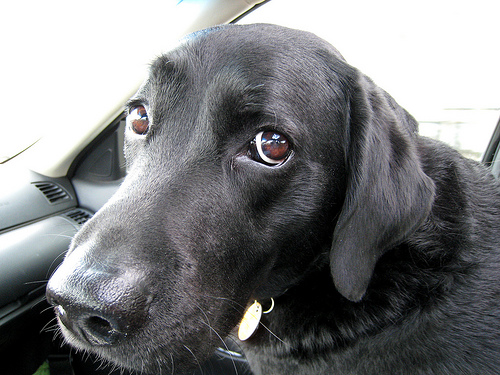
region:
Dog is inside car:
[7, 13, 487, 369]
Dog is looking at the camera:
[1, 19, 497, 372]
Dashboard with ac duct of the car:
[0, 161, 102, 296]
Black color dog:
[26, 50, 481, 367]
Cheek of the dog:
[189, 198, 243, 273]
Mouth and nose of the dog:
[41, 265, 197, 365]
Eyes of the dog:
[133, 96, 295, 176]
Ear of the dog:
[323, 79, 443, 332]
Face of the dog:
[28, 32, 406, 352]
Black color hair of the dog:
[446, 150, 490, 331]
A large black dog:
[45, 23, 495, 373]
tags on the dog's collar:
[235, 295, 270, 335]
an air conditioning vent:
[65, 205, 90, 220]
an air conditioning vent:
[31, 180, 67, 202]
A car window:
[236, 0, 496, 161]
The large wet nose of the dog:
[45, 260, 140, 345]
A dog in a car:
[42, 23, 496, 373]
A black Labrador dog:
[42, 20, 498, 372]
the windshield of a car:
[1, 0, 180, 164]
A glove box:
[0, 213, 81, 319]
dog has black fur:
[367, 190, 441, 353]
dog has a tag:
[236, 292, 280, 353]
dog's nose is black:
[62, 285, 114, 346]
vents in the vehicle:
[43, 164, 85, 230]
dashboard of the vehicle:
[11, 220, 53, 293]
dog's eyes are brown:
[264, 106, 297, 167]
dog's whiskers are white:
[203, 306, 236, 372]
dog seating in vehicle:
[391, 49, 467, 164]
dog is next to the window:
[404, 40, 481, 198]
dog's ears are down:
[343, 83, 449, 280]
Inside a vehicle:
[13, 36, 475, 368]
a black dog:
[19, 18, 417, 358]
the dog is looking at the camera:
[39, 51, 346, 366]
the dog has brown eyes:
[121, 101, 323, 174]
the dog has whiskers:
[18, 240, 298, 373]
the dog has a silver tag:
[234, 298, 285, 351]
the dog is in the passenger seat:
[15, 15, 485, 350]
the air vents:
[28, 172, 117, 244]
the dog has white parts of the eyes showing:
[242, 120, 290, 173]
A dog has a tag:
[231, 289, 293, 347]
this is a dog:
[96, 62, 475, 359]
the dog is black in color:
[131, 197, 204, 254]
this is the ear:
[339, 75, 399, 311]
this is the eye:
[246, 127, 291, 157]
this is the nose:
[35, 273, 123, 327]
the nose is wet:
[32, 295, 134, 342]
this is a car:
[21, 179, 62, 257]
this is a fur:
[176, 345, 213, 370]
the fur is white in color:
[203, 322, 237, 357]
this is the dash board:
[15, 202, 45, 247]